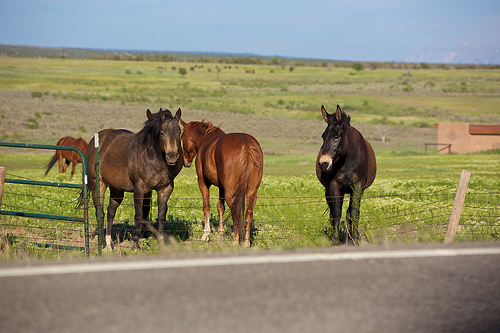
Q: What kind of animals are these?
A: Horses.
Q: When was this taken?
A: Daytime.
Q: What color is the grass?
A: Green.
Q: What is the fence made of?
A: Wire.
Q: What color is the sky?
A: Blue.